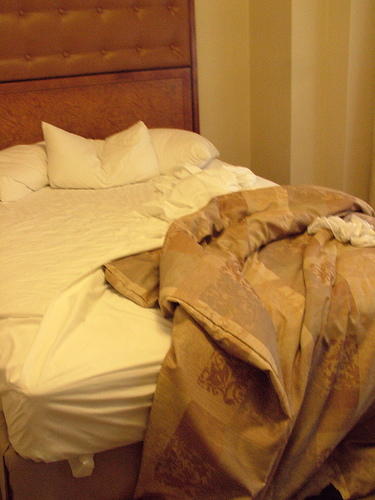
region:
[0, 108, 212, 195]
three white pillows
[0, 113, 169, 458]
a big size bed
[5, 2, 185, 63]
ten brown buttons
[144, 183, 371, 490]
a Brown bed sheet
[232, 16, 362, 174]
an ivory wall without frame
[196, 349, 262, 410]
a modern textil print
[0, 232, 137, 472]
wrinkled white bed sheet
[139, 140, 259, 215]
a white shirt on the bed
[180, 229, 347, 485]
multi-design sheet textil patterns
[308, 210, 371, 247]
a white wrinkled handkerchief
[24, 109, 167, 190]
PILLOW WITH HEAD SHAPED INDENTATION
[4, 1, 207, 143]
BROWN HEAD BOARD WITH PADDING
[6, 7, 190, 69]
TEN BUTTONS ON PADDING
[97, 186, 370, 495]
RED BROWN AND GOLD COMFORTER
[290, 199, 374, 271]
PIECE OF CLOTHING ON COMFORTER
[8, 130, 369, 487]
BED WITH SHEETS AND PILLOWS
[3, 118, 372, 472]
BED WITH BEDDING IN DISARRAY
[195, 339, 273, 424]
FLORAL PATTERN ON COMFORTER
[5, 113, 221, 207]
THREE PILLOWS AT HEAD OF BED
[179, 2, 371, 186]
BEIGE WALL WITH MULTIPLE CORNERS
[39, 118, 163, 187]
Pillow on unmade bed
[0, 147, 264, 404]
White bed covered by quilt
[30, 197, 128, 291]
White sheets on bed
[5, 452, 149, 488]
Base of bed under mattress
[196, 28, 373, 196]
Brown corrugated wall behind bed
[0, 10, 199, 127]
Brown backboard of bed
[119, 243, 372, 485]
Brown quilt is wrinkled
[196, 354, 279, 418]
Elaborate swirly pattern on quilt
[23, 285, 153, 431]
Sheets are slightly wrinkled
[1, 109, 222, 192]
Three clean, white pillows on bed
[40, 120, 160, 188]
White pillow on a bed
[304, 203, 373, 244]
White clothes on a bed spread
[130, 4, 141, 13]
Button on a brown head board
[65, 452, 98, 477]
Untucked white sheet on a bed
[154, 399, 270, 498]
Square design on a brown blanket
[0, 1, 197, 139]
Brown head board on a bed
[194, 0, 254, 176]
Wall colored tan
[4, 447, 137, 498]
Tan colored dust ruffle on a bed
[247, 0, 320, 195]
Light and dark tan corner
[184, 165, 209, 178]
White tag on a pillow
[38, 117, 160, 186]
a pillow on a bed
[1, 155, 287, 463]
a sheet covered mattress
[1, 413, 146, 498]
a bed skirt under a mattress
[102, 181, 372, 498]
a brown patterned comforter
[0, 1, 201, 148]
a padded headboard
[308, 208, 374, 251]
a white undershirt on a comforter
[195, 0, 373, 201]
a tan colored wall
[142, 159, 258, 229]
a rumpled sheet on a bed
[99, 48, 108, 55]
a decorative button on a headboard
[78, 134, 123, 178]
a dent in a pillow